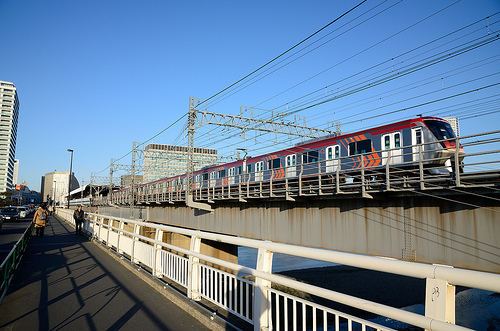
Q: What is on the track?
A: A train.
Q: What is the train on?
A: Tracks.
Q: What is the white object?
A: A guard rail.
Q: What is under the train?
A: A bridge.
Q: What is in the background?
A: Buildings.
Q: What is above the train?
A: Power lines.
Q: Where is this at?
A: Downtown.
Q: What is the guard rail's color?
A: White.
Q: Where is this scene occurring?
A: On a city street.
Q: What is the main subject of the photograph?
A: A passenger train.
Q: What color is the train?
A: Gray.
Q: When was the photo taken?
A: Day time.